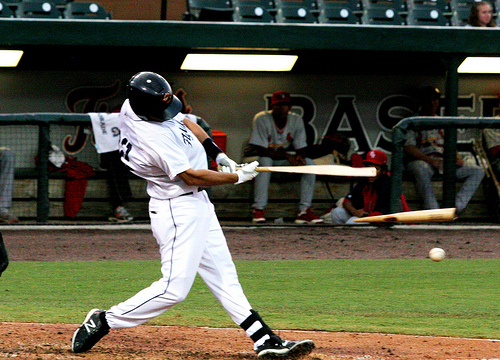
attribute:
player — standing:
[56, 62, 401, 359]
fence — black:
[2, 110, 151, 226]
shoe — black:
[255, 338, 316, 358]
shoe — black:
[253, 329, 323, 358]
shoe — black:
[64, 308, 111, 353]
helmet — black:
[103, 58, 207, 125]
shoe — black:
[294, 341, 299, 351]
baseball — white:
[428, 244, 449, 264]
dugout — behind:
[2, 8, 498, 241]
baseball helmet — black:
[127, 68, 184, 120]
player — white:
[404, 89, 489, 213]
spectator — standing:
[464, 0, 497, 27]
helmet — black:
[122, 66, 188, 127]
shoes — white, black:
[51, 307, 156, 358]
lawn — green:
[333, 281, 369, 323]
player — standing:
[257, 82, 317, 229]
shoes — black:
[38, 298, 310, 357]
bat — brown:
[241, 157, 475, 233]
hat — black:
[128, 69, 185, 122]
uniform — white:
[102, 103, 254, 328]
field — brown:
[299, 266, 441, 327]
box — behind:
[6, 321, 498, 354]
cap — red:
[269, 87, 294, 107]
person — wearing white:
[67, 70, 322, 360]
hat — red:
[270, 89, 293, 107]